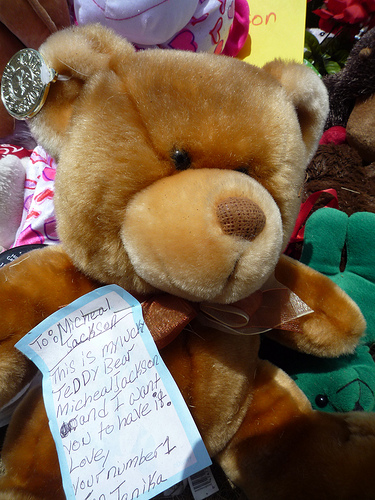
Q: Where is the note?
A: Pinned to bear.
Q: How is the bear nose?
A: Brown.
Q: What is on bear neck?
A: Tie.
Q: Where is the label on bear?
A: Ear.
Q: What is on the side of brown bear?
A: Green teddy.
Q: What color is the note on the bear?
A: Blue.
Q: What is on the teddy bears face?
A: His brown nose.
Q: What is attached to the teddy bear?
A: A hand written note.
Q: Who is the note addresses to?
A: Michael Jackson.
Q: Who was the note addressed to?
A: Michael Jackson.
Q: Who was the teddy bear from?
A: A fan.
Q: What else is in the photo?
A: Other stuffed animals.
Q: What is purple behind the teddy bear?
A: A purple toy.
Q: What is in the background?
A: Stuffed toys and flowers.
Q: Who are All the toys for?
A: Michael Jackson.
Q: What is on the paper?
A: A handwritten note.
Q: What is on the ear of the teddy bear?
A: A plastic coin painted silver.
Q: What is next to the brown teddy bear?
A: A green teddy bear upside down.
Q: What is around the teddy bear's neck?
A: A brown ribbon.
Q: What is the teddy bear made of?
A: Fabric and stuffing.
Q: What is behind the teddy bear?
A: A pink stuffed animal with a heart pattern.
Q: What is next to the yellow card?
A: A red flower.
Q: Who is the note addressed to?
A: Michael Jackson.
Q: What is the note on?
A: Paper with a blue border.